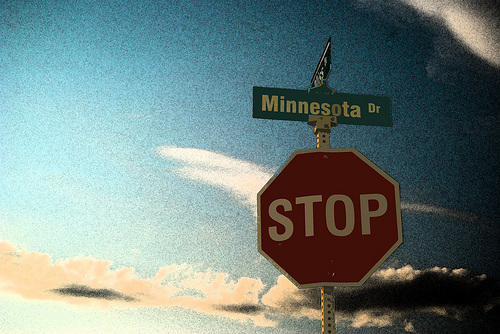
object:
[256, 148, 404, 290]
sign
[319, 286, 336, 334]
pole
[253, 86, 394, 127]
street sign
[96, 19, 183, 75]
sky